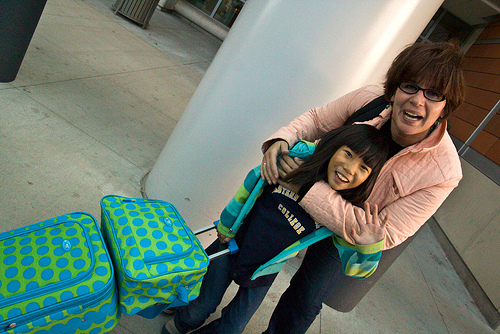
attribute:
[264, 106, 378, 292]
girl — smiling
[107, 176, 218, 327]
bag — green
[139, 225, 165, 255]
dots — blue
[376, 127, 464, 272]
jacket — peach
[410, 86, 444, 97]
frame — black